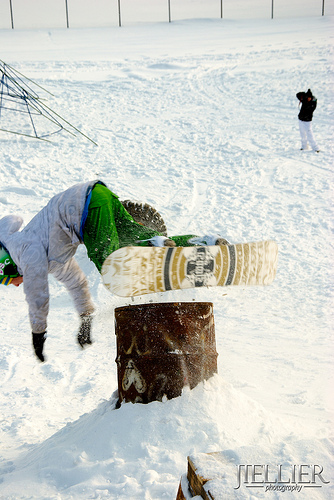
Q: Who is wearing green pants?
A: The snowboarder.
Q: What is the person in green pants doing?
A: Snowboarding.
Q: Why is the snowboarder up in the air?
A: Making a jump.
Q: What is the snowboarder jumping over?
A: A metal barrel.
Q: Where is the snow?
A: On the ground.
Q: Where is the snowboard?
A: On the boarder.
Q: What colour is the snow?
A: White.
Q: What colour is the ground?
A: White.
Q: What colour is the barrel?
A: Brown.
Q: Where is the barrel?
A: In the ground.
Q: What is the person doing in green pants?
A: Doing flips while snowboarding.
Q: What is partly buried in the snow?
A: A rusty steel drum.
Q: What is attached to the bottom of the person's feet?
A: A snowboard.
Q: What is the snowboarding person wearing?
A: A gray print jacket.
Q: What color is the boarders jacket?
A: It is white.